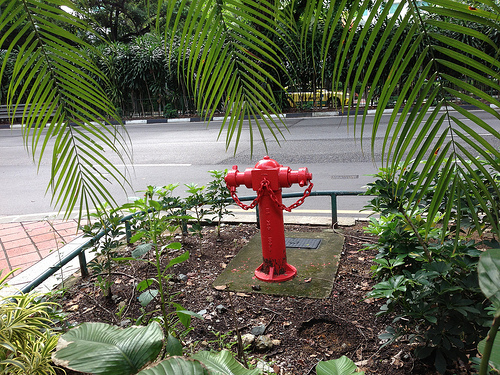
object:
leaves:
[456, 173, 485, 238]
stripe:
[74, 149, 115, 185]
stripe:
[71, 124, 109, 155]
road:
[0, 117, 500, 218]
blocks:
[1, 235, 35, 251]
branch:
[17, 0, 91, 194]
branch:
[207, 0, 252, 112]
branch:
[407, 0, 465, 178]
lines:
[136, 349, 158, 369]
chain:
[262, 179, 316, 213]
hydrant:
[224, 155, 313, 284]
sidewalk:
[0, 208, 129, 291]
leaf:
[47, 320, 166, 373]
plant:
[81, 209, 123, 298]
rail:
[1, 189, 392, 308]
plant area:
[0, 1, 500, 257]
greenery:
[114, 196, 196, 335]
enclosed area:
[9, 187, 500, 374]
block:
[213, 230, 348, 298]